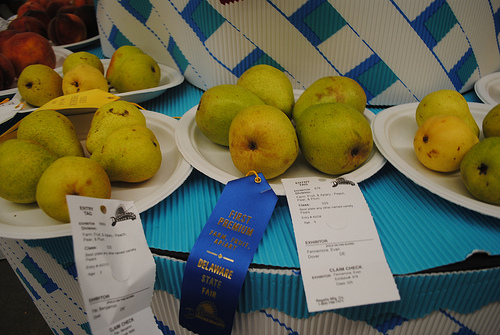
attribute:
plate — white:
[0, 109, 195, 239]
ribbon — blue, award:
[177, 171, 279, 334]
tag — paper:
[65, 193, 165, 334]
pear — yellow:
[412, 115, 479, 173]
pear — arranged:
[194, 84, 268, 147]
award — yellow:
[0, 87, 122, 138]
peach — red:
[47, 13, 87, 46]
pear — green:
[0, 138, 61, 205]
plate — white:
[369, 99, 499, 218]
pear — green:
[296, 102, 373, 175]